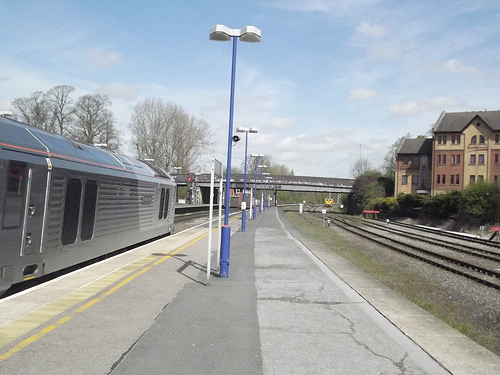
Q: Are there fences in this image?
A: No, there are no fences.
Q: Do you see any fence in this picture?
A: No, there are no fences.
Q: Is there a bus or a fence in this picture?
A: No, there are no fences or buses.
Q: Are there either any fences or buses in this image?
A: No, there are no fences or buses.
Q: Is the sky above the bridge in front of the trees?
A: Yes, the sky is above the bridge.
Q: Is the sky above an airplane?
A: No, the sky is above the bridge.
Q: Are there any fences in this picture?
A: No, there are no fences.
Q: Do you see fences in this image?
A: No, there are no fences.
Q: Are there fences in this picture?
A: No, there are no fences.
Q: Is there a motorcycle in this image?
A: No, there are no motorcycles.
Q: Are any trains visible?
A: Yes, there is a train.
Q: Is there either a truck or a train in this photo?
A: Yes, there is a train.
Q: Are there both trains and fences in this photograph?
A: No, there is a train but no fences.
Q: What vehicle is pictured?
A: The vehicle is a train.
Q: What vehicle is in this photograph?
A: The vehicle is a train.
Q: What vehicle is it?
A: The vehicle is a train.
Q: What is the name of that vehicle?
A: This is a train.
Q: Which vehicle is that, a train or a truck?
A: This is a train.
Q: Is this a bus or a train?
A: This is a train.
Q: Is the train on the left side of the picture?
A: Yes, the train is on the left of the image.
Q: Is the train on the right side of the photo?
A: No, the train is on the left of the image.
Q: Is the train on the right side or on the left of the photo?
A: The train is on the left of the image.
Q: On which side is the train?
A: The train is on the left of the image.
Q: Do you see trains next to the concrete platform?
A: Yes, there is a train next to the platform.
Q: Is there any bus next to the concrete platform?
A: No, there is a train next to the platform.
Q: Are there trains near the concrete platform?
A: Yes, there is a train near the platform.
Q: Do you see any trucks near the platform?
A: No, there is a train near the platform.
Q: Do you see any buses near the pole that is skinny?
A: No, there is a train near the pole.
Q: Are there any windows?
A: Yes, there is a window.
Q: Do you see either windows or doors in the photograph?
A: Yes, there is a window.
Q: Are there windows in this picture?
A: Yes, there is a window.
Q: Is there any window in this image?
A: Yes, there is a window.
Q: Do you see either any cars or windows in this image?
A: Yes, there is a window.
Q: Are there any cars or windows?
A: Yes, there is a window.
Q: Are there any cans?
A: No, there are no cans.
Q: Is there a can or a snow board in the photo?
A: No, there are no cans or snowboards.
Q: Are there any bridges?
A: Yes, there is a bridge.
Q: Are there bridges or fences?
A: Yes, there is a bridge.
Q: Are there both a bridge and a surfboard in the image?
A: No, there is a bridge but no surfboards.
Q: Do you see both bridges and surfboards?
A: No, there is a bridge but no surfboards.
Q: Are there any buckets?
A: No, there are no buckets.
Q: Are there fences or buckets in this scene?
A: No, there are no buckets or fences.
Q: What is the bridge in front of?
A: The bridge is in front of the trees.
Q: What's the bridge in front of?
A: The bridge is in front of the trees.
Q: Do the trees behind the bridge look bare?
A: Yes, the trees are bare.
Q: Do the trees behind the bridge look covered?
A: No, the trees are bare.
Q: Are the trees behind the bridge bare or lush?
A: The trees are bare.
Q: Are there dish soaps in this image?
A: No, there are no dish soaps.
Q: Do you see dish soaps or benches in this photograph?
A: No, there are no dish soaps or benches.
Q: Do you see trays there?
A: No, there are no trays.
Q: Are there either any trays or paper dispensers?
A: No, there are no trays or paper dispensers.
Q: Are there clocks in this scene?
A: No, there are no clocks.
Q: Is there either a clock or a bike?
A: No, there are no clocks or bikes.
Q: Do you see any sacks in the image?
A: No, there are no sacks.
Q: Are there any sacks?
A: No, there are no sacks.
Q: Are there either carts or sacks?
A: No, there are no sacks or carts.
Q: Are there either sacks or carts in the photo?
A: No, there are no sacks or carts.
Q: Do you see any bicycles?
A: No, there are no bicycles.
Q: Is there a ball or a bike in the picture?
A: No, there are no bikes or balls.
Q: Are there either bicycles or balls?
A: No, there are no bicycles or balls.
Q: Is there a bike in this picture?
A: No, there are no bikes.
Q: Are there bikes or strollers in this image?
A: No, there are no bikes or strollers.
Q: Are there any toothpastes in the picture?
A: No, there are no toothpastes.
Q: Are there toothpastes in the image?
A: No, there are no toothpastes.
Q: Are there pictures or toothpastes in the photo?
A: No, there are no toothpastes or pictures.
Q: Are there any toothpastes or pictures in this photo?
A: No, there are no toothpastes or pictures.